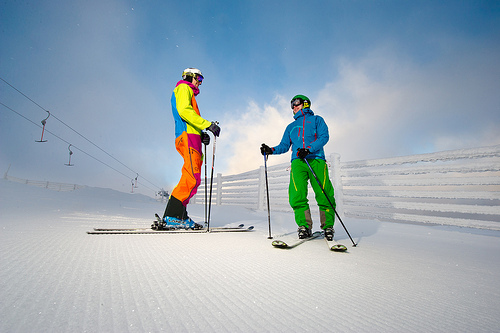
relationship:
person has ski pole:
[152, 64, 221, 229] [195, 126, 213, 233]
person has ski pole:
[152, 64, 221, 229] [207, 130, 220, 235]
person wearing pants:
[255, 94, 343, 242] [284, 157, 336, 228]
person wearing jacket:
[255, 94, 343, 242] [266, 108, 329, 161]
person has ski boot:
[152, 64, 221, 229] [159, 213, 200, 229]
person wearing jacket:
[152, 64, 221, 229] [169, 81, 210, 134]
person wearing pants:
[152, 64, 221, 229] [163, 132, 205, 229]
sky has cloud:
[2, 1, 494, 158] [209, 39, 441, 163]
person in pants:
[255, 94, 343, 242] [284, 157, 336, 228]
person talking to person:
[152, 64, 221, 229] [255, 94, 343, 242]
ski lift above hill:
[0, 76, 175, 211] [1, 179, 499, 329]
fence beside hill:
[188, 150, 500, 232] [1, 179, 499, 329]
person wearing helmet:
[152, 64, 221, 229] [289, 94, 312, 108]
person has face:
[152, 64, 221, 229] [193, 72, 203, 90]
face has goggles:
[193, 72, 203, 90] [182, 71, 203, 83]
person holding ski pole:
[152, 64, 221, 229] [195, 126, 213, 233]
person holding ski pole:
[152, 64, 221, 229] [207, 130, 220, 235]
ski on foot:
[84, 227, 254, 234] [162, 216, 195, 226]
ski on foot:
[93, 222, 249, 231] [162, 216, 195, 226]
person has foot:
[152, 64, 221, 229] [162, 216, 195, 226]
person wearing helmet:
[152, 64, 221, 229] [183, 68, 203, 81]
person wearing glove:
[152, 64, 221, 229] [207, 121, 221, 136]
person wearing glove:
[152, 64, 221, 229] [197, 132, 209, 146]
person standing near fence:
[152, 64, 221, 229] [188, 150, 500, 232]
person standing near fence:
[255, 94, 343, 242] [188, 150, 500, 232]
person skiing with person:
[152, 64, 221, 229] [255, 94, 343, 242]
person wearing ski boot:
[152, 64, 221, 229] [159, 213, 200, 229]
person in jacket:
[152, 64, 221, 229] [169, 81, 210, 134]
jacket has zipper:
[266, 108, 329, 161] [299, 106, 308, 158]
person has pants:
[255, 94, 343, 242] [284, 157, 336, 228]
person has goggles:
[152, 64, 221, 229] [182, 71, 203, 83]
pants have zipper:
[284, 157, 336, 228] [288, 168, 300, 195]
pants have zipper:
[284, 157, 336, 228] [317, 160, 328, 198]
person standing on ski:
[152, 64, 221, 229] [84, 227, 254, 234]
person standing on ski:
[152, 64, 221, 229] [93, 222, 249, 231]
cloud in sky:
[209, 39, 441, 163] [2, 1, 494, 158]